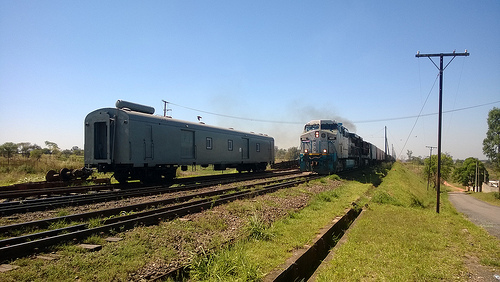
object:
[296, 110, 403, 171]
train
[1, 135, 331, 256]
rails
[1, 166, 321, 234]
grass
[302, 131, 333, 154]
headlights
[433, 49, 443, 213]
utility pole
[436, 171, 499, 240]
road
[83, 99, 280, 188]
train car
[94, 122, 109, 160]
door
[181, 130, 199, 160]
door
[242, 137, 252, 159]
door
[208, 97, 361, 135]
smoke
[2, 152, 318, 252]
tracks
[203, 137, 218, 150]
windows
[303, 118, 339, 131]
windshield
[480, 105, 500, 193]
trees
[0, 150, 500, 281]
grass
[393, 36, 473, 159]
power line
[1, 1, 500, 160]
sky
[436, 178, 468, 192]
trail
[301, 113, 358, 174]
engine car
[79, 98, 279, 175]
locomotive